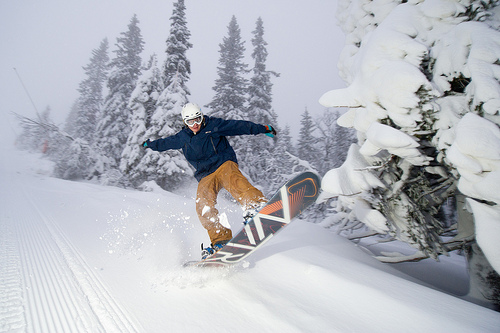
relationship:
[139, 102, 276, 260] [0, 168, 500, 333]
man snowboarding down snow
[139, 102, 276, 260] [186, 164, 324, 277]
man on snowboard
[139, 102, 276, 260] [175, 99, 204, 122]
man wearing helmet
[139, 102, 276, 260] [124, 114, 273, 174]
man wearing top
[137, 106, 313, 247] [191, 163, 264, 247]
man wearing pants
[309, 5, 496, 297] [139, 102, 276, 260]
tree next to man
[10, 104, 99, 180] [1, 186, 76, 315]
tree has fallen onto a lines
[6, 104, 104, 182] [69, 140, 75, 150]
tree covered in snow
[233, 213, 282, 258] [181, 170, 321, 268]
stripes across bottom of board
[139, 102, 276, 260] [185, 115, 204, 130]
man wearing goggles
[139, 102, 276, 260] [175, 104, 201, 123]
man wearing helmet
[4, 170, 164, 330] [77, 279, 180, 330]
lines made in snow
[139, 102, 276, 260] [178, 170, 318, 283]
man tipping up front of board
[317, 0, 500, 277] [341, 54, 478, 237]
snow on branches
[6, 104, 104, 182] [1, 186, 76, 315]
tree leaning over into lines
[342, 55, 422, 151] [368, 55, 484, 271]
snow covers branches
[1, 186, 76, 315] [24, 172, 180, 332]
lines on snow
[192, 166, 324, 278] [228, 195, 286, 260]
snow board has bottom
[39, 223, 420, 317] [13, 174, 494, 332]
snow on ground